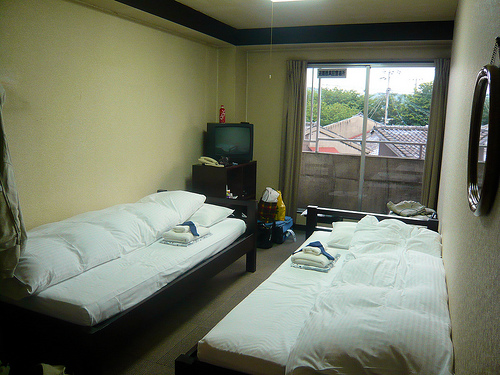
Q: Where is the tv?
A: In the corner.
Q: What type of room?
A: Bedroom.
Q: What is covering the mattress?
A: Sheets.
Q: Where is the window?
A: Next to the tv.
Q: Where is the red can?
A: On the tv.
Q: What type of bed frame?
A: Wood.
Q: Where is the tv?
A: In the corner.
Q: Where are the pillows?
A: On the bed.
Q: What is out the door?
A: Balcony.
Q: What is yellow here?
A: The wall.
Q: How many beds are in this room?
A: Two.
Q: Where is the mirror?
A: On the wall.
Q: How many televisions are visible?
A: One.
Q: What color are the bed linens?
A: White.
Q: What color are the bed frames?
A: Black.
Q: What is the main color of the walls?
A: Tan.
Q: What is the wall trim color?
A: Black.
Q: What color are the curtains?
A: Tan.